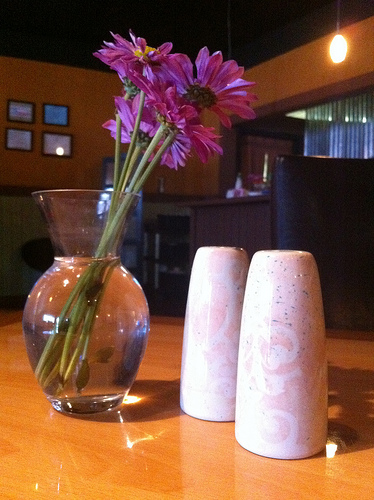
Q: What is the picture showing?
A: It is showing a restaurant.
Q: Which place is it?
A: It is a restaurant.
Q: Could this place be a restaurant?
A: Yes, it is a restaurant.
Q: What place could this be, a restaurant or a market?
A: It is a restaurant.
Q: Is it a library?
A: No, it is a restaurant.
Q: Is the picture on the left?
A: Yes, the picture is on the left of the image.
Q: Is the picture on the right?
A: No, the picture is on the left of the image.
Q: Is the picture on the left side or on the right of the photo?
A: The picture is on the left of the image.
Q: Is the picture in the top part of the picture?
A: Yes, the picture is in the top of the image.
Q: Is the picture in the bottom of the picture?
A: No, the picture is in the top of the image.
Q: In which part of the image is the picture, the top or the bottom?
A: The picture is in the top of the image.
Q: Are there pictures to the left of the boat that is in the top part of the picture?
A: Yes, there is a picture to the left of the boat.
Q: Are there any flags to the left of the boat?
A: No, there is a picture to the left of the boat.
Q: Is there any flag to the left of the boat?
A: No, there is a picture to the left of the boat.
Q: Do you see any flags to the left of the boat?
A: No, there is a picture to the left of the boat.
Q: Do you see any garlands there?
A: No, there are no garlands.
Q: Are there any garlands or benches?
A: No, there are no garlands or benches.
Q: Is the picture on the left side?
A: Yes, the picture is on the left of the image.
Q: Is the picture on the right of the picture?
A: No, the picture is on the left of the image.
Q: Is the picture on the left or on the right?
A: The picture is on the left of the image.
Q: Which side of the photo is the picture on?
A: The picture is on the left of the image.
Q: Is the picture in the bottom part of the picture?
A: No, the picture is in the top of the image.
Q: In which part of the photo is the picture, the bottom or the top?
A: The picture is in the top of the image.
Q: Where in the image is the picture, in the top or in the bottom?
A: The picture is in the top of the image.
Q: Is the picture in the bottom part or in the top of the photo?
A: The picture is in the top of the image.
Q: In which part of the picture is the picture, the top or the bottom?
A: The picture is in the top of the image.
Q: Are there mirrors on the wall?
A: No, there is a picture on the wall.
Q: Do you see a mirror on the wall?
A: No, there is a picture on the wall.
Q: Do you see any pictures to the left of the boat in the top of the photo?
A: Yes, there is a picture to the left of the boat.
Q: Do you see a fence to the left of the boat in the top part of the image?
A: No, there is a picture to the left of the boat.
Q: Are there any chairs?
A: No, there are no chairs.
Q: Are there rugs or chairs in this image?
A: No, there are no chairs or rugs.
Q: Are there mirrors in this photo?
A: No, there are no mirrors.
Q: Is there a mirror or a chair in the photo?
A: No, there are no mirrors or chairs.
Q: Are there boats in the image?
A: Yes, there is a boat.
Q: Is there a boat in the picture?
A: Yes, there is a boat.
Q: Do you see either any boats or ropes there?
A: Yes, there is a boat.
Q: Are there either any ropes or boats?
A: Yes, there is a boat.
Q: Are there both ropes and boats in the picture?
A: No, there is a boat but no ropes.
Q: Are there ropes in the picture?
A: No, there are no ropes.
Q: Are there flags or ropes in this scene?
A: No, there are no ropes or flags.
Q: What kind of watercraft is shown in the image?
A: The watercraft is a boat.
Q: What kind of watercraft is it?
A: The watercraft is a boat.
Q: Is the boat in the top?
A: Yes, the boat is in the top of the image.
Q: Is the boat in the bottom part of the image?
A: No, the boat is in the top of the image.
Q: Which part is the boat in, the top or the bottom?
A: The boat is in the top of the image.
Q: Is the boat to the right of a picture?
A: Yes, the boat is to the right of a picture.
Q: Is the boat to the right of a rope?
A: No, the boat is to the right of a picture.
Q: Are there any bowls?
A: No, there are no bowls.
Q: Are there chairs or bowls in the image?
A: No, there are no bowls or chairs.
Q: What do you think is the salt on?
A: The salt is on the table.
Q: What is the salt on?
A: The salt is on the table.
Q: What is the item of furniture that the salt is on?
A: The piece of furniture is a table.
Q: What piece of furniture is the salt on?
A: The salt is on the table.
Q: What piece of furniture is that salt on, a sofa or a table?
A: The salt is on a table.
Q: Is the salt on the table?
A: Yes, the salt is on the table.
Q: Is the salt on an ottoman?
A: No, the salt is on the table.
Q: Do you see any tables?
A: Yes, there is a table.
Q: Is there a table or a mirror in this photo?
A: Yes, there is a table.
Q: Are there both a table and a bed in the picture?
A: No, there is a table but no beds.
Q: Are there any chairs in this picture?
A: No, there are no chairs.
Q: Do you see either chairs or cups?
A: No, there are no chairs or cups.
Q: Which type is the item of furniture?
A: The piece of furniture is a table.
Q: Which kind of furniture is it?
A: The piece of furniture is a table.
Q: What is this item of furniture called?
A: This is a table.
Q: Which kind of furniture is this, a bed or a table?
A: This is a table.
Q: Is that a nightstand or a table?
A: That is a table.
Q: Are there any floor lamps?
A: No, there are no floor lamps.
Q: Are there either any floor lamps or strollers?
A: No, there are no floor lamps or strollers.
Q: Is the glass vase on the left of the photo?
A: Yes, the vase is on the left of the image.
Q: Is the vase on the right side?
A: No, the vase is on the left of the image.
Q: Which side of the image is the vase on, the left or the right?
A: The vase is on the left of the image.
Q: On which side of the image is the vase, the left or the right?
A: The vase is on the left of the image.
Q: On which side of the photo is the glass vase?
A: The vase is on the left of the image.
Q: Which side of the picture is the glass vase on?
A: The vase is on the left of the image.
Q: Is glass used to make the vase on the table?
A: Yes, the vase is made of glass.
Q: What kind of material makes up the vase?
A: The vase is made of glass.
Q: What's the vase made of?
A: The vase is made of glass.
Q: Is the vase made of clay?
A: No, the vase is made of glass.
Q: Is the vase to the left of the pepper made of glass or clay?
A: The vase is made of glass.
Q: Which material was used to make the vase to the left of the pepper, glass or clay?
A: The vase is made of glass.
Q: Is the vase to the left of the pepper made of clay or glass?
A: The vase is made of glass.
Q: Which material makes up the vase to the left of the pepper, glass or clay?
A: The vase is made of glass.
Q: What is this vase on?
A: The vase is on the table.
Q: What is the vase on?
A: The vase is on the table.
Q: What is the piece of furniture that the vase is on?
A: The piece of furniture is a table.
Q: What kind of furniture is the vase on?
A: The vase is on the table.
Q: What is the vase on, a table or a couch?
A: The vase is on a table.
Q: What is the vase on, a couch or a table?
A: The vase is on a table.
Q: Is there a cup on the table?
A: No, there is a vase on the table.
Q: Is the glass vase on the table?
A: Yes, the vase is on the table.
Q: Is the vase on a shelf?
A: No, the vase is on the table.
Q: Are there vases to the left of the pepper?
A: Yes, there is a vase to the left of the pepper.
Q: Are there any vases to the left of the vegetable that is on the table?
A: Yes, there is a vase to the left of the pepper.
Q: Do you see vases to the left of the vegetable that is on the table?
A: Yes, there is a vase to the left of the pepper.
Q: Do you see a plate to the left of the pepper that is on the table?
A: No, there is a vase to the left of the pepper.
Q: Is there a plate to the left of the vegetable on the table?
A: No, there is a vase to the left of the pepper.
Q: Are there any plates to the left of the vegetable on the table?
A: No, there is a vase to the left of the pepper.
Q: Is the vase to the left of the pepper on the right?
A: Yes, the vase is to the left of the pepper.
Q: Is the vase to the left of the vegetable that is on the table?
A: Yes, the vase is to the left of the pepper.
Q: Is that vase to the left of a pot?
A: No, the vase is to the left of the pepper.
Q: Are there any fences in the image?
A: No, there are no fences.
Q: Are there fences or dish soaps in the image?
A: No, there are no fences or dish soaps.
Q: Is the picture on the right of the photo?
A: No, the picture is on the left of the image.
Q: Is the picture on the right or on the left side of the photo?
A: The picture is on the left of the image.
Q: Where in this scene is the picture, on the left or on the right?
A: The picture is on the left of the image.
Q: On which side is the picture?
A: The picture is on the left of the image.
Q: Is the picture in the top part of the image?
A: Yes, the picture is in the top of the image.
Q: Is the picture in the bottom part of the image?
A: No, the picture is in the top of the image.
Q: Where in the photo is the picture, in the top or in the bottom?
A: The picture is in the top of the image.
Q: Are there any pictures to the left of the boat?
A: Yes, there is a picture to the left of the boat.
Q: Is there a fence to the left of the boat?
A: No, there is a picture to the left of the boat.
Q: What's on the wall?
A: The picture is on the wall.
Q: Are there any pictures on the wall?
A: Yes, there is a picture on the wall.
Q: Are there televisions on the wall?
A: No, there is a picture on the wall.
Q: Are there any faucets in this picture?
A: No, there are no faucets.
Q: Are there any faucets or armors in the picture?
A: No, there are no faucets or armors.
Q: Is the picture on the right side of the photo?
A: No, the picture is on the left of the image.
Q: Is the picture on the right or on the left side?
A: The picture is on the left of the image.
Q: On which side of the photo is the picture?
A: The picture is on the left of the image.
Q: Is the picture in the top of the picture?
A: Yes, the picture is in the top of the image.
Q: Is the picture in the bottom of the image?
A: No, the picture is in the top of the image.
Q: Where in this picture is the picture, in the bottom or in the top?
A: The picture is in the top of the image.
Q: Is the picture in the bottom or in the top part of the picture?
A: The picture is in the top of the image.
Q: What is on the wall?
A: The picture is on the wall.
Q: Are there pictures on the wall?
A: Yes, there is a picture on the wall.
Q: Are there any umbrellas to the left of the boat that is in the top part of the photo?
A: No, there is a picture to the left of the boat.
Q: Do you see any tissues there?
A: No, there are no tissues.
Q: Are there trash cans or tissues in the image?
A: No, there are no tissues or trash cans.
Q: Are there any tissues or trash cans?
A: No, there are no tissues or trash cans.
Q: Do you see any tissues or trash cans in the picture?
A: No, there are no tissues or trash cans.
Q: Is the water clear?
A: Yes, the water is clear.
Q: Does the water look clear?
A: Yes, the water is clear.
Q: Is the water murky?
A: No, the water is clear.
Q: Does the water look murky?
A: No, the water is clear.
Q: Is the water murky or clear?
A: The water is clear.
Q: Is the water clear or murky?
A: The water is clear.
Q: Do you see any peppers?
A: Yes, there is a pepper.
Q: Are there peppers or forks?
A: Yes, there is a pepper.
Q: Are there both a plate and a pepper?
A: No, there is a pepper but no plates.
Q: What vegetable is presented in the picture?
A: The vegetable is a pepper.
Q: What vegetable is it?
A: The vegetable is a pepper.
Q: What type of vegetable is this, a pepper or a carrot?
A: This is a pepper.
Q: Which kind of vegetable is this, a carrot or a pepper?
A: This is a pepper.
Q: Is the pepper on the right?
A: Yes, the pepper is on the right of the image.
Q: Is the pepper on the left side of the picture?
A: No, the pepper is on the right of the image.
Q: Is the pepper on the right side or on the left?
A: The pepper is on the right of the image.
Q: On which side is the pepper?
A: The pepper is on the right of the image.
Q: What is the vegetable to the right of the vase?
A: The vegetable is a pepper.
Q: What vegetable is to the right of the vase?
A: The vegetable is a pepper.